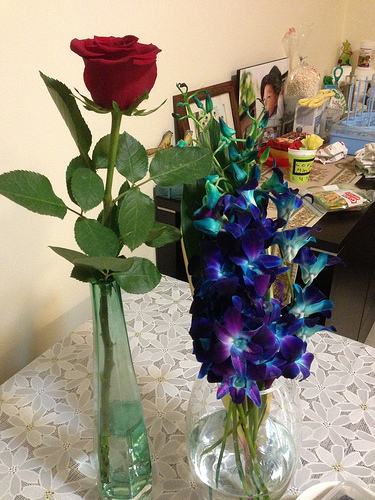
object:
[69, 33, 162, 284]
rose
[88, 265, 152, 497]
vase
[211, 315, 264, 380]
flowers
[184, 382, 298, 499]
vase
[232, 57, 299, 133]
photo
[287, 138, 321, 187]
container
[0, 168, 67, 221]
leaves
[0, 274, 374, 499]
table cloth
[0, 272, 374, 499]
table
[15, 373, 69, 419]
flower pattern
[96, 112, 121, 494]
long stem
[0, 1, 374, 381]
wall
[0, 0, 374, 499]
background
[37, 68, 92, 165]
leaf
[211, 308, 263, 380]
flower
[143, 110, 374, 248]
counter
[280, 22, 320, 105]
bag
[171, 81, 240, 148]
picture